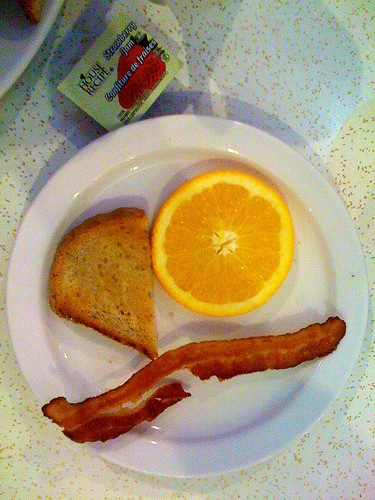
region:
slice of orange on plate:
[161, 176, 277, 309]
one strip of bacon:
[113, 306, 309, 419]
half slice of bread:
[49, 190, 169, 369]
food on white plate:
[8, 189, 279, 464]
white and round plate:
[33, 85, 350, 472]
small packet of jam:
[58, 50, 140, 116]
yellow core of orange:
[204, 215, 250, 278]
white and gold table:
[231, 34, 327, 111]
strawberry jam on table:
[51, 38, 179, 124]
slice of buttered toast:
[76, 178, 164, 344]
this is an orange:
[161, 182, 282, 296]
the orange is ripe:
[158, 175, 279, 300]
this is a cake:
[42, 204, 143, 330]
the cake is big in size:
[55, 208, 146, 330]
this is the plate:
[211, 383, 275, 465]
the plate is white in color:
[207, 386, 286, 452]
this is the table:
[307, 426, 362, 498]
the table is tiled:
[319, 416, 365, 487]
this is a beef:
[184, 309, 344, 384]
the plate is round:
[312, 224, 357, 280]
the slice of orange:
[150, 170, 294, 317]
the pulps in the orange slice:
[165, 182, 279, 305]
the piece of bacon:
[40, 315, 346, 443]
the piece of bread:
[49, 207, 158, 360]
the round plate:
[5, 113, 368, 476]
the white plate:
[6, 114, 368, 477]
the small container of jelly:
[58, 11, 182, 130]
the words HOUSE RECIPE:
[78, 62, 110, 95]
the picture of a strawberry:
[115, 33, 164, 108]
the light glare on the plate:
[226, 147, 239, 155]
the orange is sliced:
[151, 181, 292, 296]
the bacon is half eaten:
[54, 324, 340, 448]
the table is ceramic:
[309, 447, 373, 492]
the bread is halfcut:
[46, 227, 157, 350]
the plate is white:
[0, 137, 367, 473]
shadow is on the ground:
[224, 24, 338, 128]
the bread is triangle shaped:
[55, 217, 165, 357]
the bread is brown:
[45, 206, 164, 357]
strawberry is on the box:
[109, 47, 163, 95]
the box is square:
[58, 14, 181, 131]